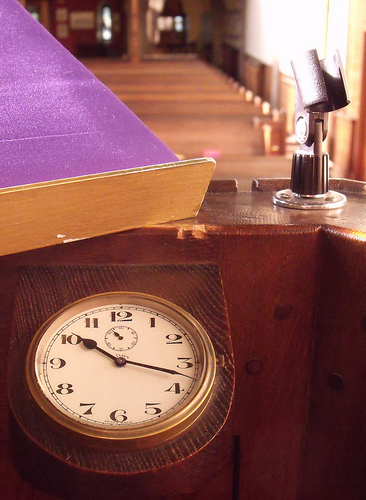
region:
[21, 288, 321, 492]
An analog clock that reads 10:17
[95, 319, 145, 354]
The second hand in a Timex clock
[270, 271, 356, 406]
wooden pegs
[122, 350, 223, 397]
the minute hand on a Timex clock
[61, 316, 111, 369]
the hour hand on a Timex clock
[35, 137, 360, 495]
a preacher's pulpit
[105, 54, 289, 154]
a row of pews in a church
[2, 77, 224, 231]
a purple stand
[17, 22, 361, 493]
the inside of a church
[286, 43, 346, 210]
a microphone stand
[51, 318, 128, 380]
the short hour hand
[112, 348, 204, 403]
the longer minute hand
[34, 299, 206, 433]
the whole clock face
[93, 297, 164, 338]
the number between eleven and one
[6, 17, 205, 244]
the purple speakers stand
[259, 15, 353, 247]
the silver microphone holder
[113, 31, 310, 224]
the faded pews in the background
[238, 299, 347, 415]
three wooden buttons on the wood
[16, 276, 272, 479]
the entire wooden clock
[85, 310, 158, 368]
the second hand counter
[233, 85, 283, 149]
lights on the wooden floor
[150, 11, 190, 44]
large brown door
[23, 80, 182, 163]
purple top of object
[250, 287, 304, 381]
small round spots on wood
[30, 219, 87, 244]
tiny white spots on wood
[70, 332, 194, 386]
black hands on clock face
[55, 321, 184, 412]
white face on the clock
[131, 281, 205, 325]
gold rim on the clock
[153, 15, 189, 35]
windows in the far distance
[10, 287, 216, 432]
black numbers on the clock face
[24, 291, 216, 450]
a brown and white clock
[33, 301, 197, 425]
A clock with round face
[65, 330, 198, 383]
black hour and minute hands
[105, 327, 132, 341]
a small second clock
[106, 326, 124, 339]
a small black second hand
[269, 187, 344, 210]
A round silver base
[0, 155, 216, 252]
a square brown wood piece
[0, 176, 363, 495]
A small brown stand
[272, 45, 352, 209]
a metal round holder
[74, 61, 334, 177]
A brown wooden floor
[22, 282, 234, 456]
the clock reads 18 minutes past ten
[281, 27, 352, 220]
this appears to be a microphone stand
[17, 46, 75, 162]
this appears to be purple cloth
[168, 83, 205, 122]
the floor is made of wood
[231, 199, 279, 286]
the desk is wooden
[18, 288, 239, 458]
the clock is framed in gold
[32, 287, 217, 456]
the face of the clock is white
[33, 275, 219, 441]
the clock numbers are black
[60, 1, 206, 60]
the background is out of focus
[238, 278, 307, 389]
this wooden piece is put together with pegs